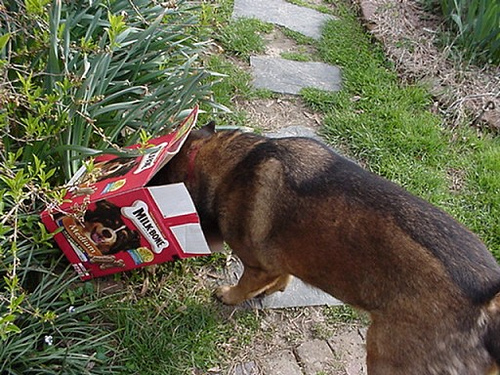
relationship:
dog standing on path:
[171, 118, 498, 373] [215, 5, 381, 317]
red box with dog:
[37, 101, 225, 282] [47, 198, 144, 265]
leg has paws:
[231, 262, 280, 299] [213, 284, 239, 304]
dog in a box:
[171, 118, 498, 373] [38, 125, 223, 277]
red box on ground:
[41, 104, 220, 282] [293, 47, 460, 155]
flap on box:
[139, 188, 205, 268] [38, 125, 223, 277]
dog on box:
[78, 200, 143, 254] [36, 101, 226, 285]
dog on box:
[79, 151, 132, 183] [36, 101, 226, 285]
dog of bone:
[47, 198, 144, 265] [121, 191, 188, 253]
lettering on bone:
[134, 207, 167, 248] [117, 203, 175, 257]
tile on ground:
[229, 1, 337, 48] [121, 1, 498, 369]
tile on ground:
[246, 55, 346, 102] [121, 1, 498, 369]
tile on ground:
[261, 122, 329, 146] [121, 1, 498, 369]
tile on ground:
[234, 259, 346, 311] [121, 1, 498, 369]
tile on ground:
[298, 337, 343, 374] [121, 1, 498, 369]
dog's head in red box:
[148, 118, 216, 233] [37, 101, 225, 282]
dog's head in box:
[148, 109, 251, 249] [36, 101, 226, 285]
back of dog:
[293, 143, 480, 252] [166, 118, 500, 374]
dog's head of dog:
[148, 118, 216, 233] [171, 118, 498, 373]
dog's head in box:
[148, 118, 216, 233] [44, 130, 187, 264]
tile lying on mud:
[293, 337, 345, 374] [261, 315, 291, 350]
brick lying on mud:
[324, 330, 376, 374] [261, 315, 291, 350]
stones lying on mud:
[251, 347, 305, 374] [261, 315, 291, 350]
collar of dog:
[175, 125, 241, 227] [137, 81, 497, 360]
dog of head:
[47, 198, 144, 265] [81, 181, 146, 266]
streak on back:
[260, 119, 494, 320] [184, 104, 491, 310]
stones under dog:
[231, 308, 368, 373] [171, 118, 498, 373]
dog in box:
[171, 118, 498, 373] [36, 101, 226, 285]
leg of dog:
[213, 262, 279, 308] [171, 118, 498, 373]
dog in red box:
[166, 118, 500, 374] [37, 101, 225, 282]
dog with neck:
[171, 118, 498, 373] [185, 130, 260, 228]